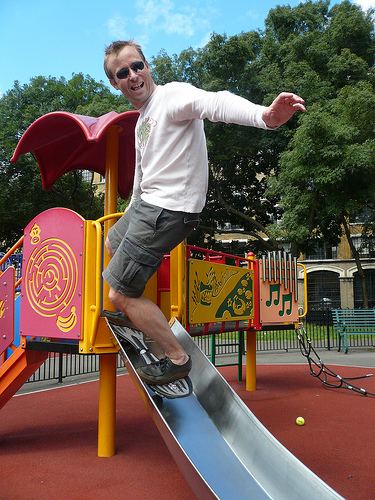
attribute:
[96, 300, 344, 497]
slide — gray, silver, metal, smooth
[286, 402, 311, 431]
tennis ball — small, yellow, green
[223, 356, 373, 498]
ground — red, rubber, smooth, clean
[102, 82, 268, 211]
sweater — white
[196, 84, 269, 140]
sleeve — long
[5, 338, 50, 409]
stairs — orange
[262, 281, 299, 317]
musical notes — green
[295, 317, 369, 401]
ladder — rope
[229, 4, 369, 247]
trees — big, green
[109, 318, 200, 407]
skateboard — black, white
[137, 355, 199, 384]
shoe — black, brown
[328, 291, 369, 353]
bench — green, blue, metal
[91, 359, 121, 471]
pole — yellow, large, metal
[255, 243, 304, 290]
instruments — metal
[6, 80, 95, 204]
bush — green